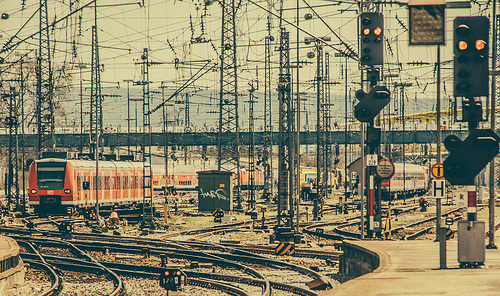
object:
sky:
[1, 1, 499, 131]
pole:
[365, 177, 376, 240]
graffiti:
[199, 186, 229, 202]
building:
[197, 171, 230, 213]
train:
[31, 146, 350, 207]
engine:
[31, 159, 180, 214]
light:
[65, 189, 67, 194]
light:
[31, 190, 35, 193]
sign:
[430, 165, 444, 179]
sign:
[431, 179, 446, 199]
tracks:
[4, 194, 497, 296]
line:
[93, 10, 226, 25]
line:
[61, 27, 129, 69]